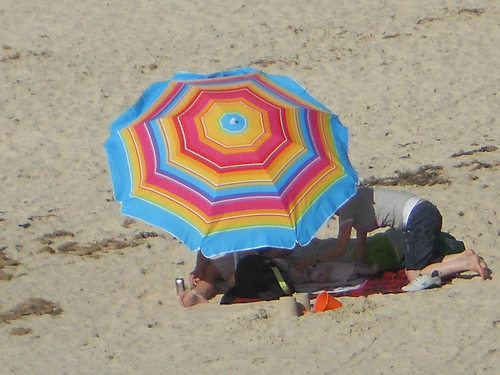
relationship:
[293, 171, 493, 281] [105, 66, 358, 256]
person under umbrella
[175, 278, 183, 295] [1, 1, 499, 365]
can on ground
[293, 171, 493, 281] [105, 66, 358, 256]
person near umbrella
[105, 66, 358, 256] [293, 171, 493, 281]
umbrella near person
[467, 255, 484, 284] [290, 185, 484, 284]
foot of person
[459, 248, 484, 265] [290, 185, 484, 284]
foot of person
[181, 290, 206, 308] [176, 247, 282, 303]
foot of person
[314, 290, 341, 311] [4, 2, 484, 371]
bucket on beach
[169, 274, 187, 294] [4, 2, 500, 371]
can in beach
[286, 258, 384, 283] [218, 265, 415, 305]
baby on blanket